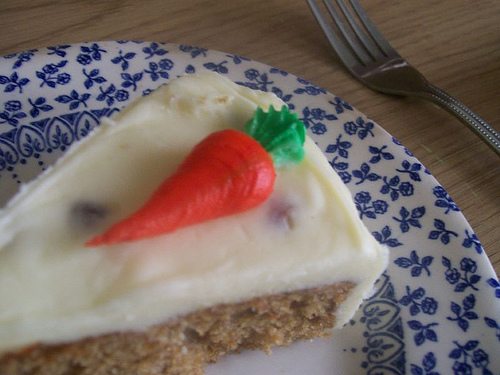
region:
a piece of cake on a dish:
[2, 22, 495, 370]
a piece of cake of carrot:
[10, 55, 390, 370]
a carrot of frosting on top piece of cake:
[62, 95, 322, 270]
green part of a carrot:
[235, 93, 313, 178]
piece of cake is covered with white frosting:
[10, 60, 401, 373]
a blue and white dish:
[0, 35, 499, 374]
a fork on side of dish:
[309, 2, 499, 167]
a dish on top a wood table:
[3, 4, 499, 374]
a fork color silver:
[302, 0, 499, 160]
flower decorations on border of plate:
[3, 40, 122, 115]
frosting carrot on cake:
[81, 112, 286, 268]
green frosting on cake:
[243, 105, 305, 165]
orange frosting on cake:
[85, 123, 277, 249]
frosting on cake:
[2, 66, 379, 347]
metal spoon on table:
[300, 8, 497, 154]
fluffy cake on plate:
[17, 294, 343, 373]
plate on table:
[12, 52, 490, 373]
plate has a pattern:
[5, 51, 497, 354]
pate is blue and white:
[12, 43, 492, 371]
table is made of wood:
[24, 9, 495, 165]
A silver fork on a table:
[306, 0, 496, 148]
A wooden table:
[0, 0, 495, 272]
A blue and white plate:
[0, 35, 497, 370]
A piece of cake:
[0, 62, 390, 369]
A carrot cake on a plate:
[0, 65, 390, 370]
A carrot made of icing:
[86, 101, 301, 242]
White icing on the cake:
[0, 75, 390, 350]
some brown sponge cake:
[0, 281, 345, 368]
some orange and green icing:
[80, 100, 305, 241]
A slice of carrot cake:
[0, 65, 388, 373]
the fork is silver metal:
[310, 0, 498, 158]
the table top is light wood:
[1, 4, 498, 274]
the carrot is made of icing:
[79, 103, 311, 251]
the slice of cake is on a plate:
[0, 70, 390, 365]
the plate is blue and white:
[2, 42, 498, 374]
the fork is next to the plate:
[305, 1, 497, 166]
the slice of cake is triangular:
[2, 59, 390, 370]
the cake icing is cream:
[2, 62, 380, 337]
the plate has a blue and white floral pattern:
[0, 42, 497, 373]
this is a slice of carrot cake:
[2, 65, 392, 367]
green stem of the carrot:
[253, 108, 313, 165]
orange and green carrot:
[75, 98, 302, 266]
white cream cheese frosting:
[282, 213, 364, 269]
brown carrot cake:
[212, 300, 349, 345]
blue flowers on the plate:
[373, 171, 455, 254]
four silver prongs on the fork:
[305, 8, 395, 67]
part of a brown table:
[188, 15, 281, 44]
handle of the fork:
[426, 83, 498, 139]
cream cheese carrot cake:
[5, 68, 390, 367]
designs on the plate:
[10, 136, 53, 170]